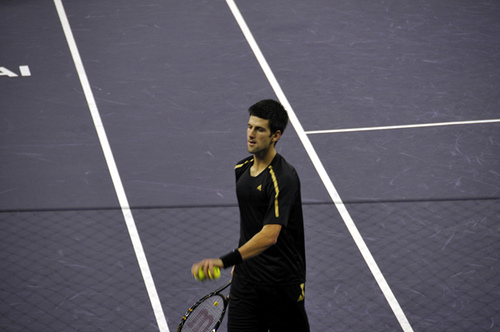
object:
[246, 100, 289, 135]
man's hair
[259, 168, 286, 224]
stripe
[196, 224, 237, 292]
balls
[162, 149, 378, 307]
uniform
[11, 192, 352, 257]
fence shadow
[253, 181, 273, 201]
gold logo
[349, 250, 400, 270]
white line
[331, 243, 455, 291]
court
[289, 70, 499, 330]
tennis court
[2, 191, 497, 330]
fence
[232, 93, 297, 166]
head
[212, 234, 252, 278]
wrist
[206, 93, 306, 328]
man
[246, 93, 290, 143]
hair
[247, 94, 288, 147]
hair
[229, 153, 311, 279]
shirt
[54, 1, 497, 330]
lines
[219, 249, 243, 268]
wristband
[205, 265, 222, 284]
ball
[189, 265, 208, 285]
ball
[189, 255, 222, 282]
hand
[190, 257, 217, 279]
fingers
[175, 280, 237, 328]
tennis racket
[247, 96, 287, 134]
hair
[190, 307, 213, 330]
letter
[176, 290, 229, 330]
racket strings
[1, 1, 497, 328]
ground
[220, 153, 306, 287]
top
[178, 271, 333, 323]
shorts